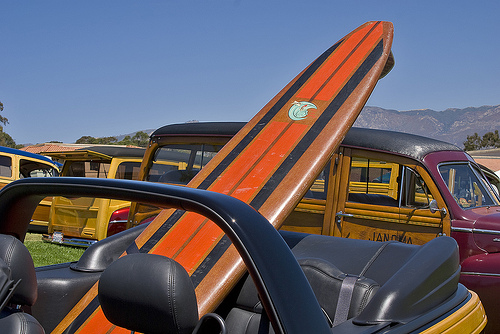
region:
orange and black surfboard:
[267, 36, 375, 151]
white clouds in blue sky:
[12, 11, 47, 68]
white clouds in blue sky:
[20, 69, 97, 123]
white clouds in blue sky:
[72, 18, 140, 69]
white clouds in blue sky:
[108, 25, 180, 70]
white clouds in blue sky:
[127, 79, 195, 124]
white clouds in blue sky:
[187, 12, 304, 74]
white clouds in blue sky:
[197, 48, 249, 95]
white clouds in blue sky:
[402, 18, 463, 53]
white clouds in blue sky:
[424, 56, 489, 78]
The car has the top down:
[41, 128, 485, 332]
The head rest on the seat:
[92, 238, 209, 331]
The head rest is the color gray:
[90, 256, 204, 331]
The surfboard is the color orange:
[53, 19, 403, 331]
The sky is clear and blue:
[26, 12, 307, 100]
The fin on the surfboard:
[374, 40, 398, 85]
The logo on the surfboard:
[282, 92, 321, 130]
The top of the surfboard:
[273, 13, 417, 120]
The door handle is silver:
[331, 205, 358, 227]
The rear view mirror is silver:
[426, 196, 451, 218]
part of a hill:
[438, 120, 441, 129]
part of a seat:
[150, 292, 158, 310]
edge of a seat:
[396, 275, 404, 280]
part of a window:
[465, 170, 475, 182]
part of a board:
[296, 181, 300, 188]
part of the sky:
[113, 106, 120, 120]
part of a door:
[347, 167, 360, 192]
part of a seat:
[171, 282, 183, 297]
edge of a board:
[295, 180, 297, 186]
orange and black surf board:
[75, 14, 414, 327]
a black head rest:
[105, 256, 195, 324]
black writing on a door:
[366, 228, 417, 241]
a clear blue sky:
[34, 2, 266, 99]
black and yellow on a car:
[378, 246, 499, 328]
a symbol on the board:
[276, 94, 315, 125]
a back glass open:
[34, 139, 106, 166]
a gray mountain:
[381, 96, 498, 132]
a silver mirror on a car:
[427, 195, 450, 214]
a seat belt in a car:
[328, 272, 353, 325]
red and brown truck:
[374, 132, 469, 226]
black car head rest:
[87, 242, 196, 323]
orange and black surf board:
[238, 17, 398, 207]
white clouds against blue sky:
[8, 8, 67, 60]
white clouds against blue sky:
[29, 45, 69, 88]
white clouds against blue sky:
[77, 11, 137, 78]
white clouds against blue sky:
[94, 77, 135, 111]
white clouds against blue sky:
[144, 60, 234, 113]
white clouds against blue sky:
[189, 11, 266, 71]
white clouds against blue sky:
[416, 18, 498, 69]